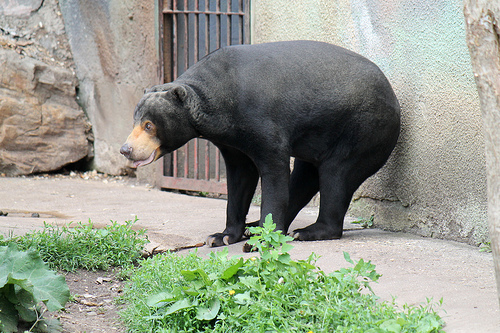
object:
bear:
[119, 39, 400, 252]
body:
[251, 75, 332, 121]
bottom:
[153, 176, 228, 194]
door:
[156, 0, 250, 200]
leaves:
[245, 213, 294, 253]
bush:
[146, 212, 383, 332]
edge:
[35, 210, 41, 214]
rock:
[147, 225, 200, 255]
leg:
[203, 167, 256, 252]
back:
[216, 57, 319, 90]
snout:
[121, 143, 135, 156]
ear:
[171, 84, 188, 106]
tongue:
[126, 162, 140, 173]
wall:
[373, 20, 459, 58]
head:
[120, 83, 198, 167]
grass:
[0, 215, 151, 272]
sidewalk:
[57, 194, 135, 215]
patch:
[80, 277, 117, 301]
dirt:
[65, 314, 105, 332]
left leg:
[254, 154, 290, 234]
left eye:
[144, 117, 159, 133]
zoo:
[0, 0, 500, 333]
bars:
[155, 0, 250, 195]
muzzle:
[120, 135, 161, 167]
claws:
[207, 234, 230, 247]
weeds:
[15, 251, 78, 320]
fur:
[220, 122, 267, 146]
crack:
[174, 239, 197, 257]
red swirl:
[98, 39, 123, 85]